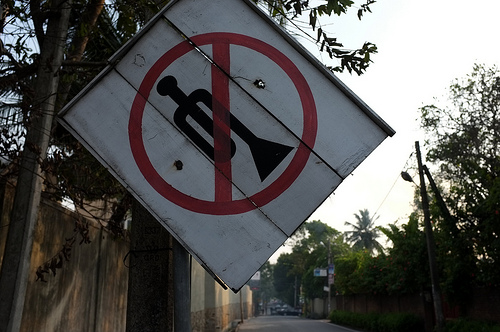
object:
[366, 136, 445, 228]
electric wire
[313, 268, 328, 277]
signs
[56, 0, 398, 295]
signs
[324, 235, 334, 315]
pole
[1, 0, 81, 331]
pole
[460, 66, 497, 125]
green parts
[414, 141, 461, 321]
pole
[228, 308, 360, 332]
street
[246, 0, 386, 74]
tree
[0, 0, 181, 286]
tree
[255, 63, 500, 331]
tree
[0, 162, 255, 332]
fence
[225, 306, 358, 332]
road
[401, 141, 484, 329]
street light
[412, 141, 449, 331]
light post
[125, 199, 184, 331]
pole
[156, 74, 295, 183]
black trumpet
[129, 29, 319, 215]
print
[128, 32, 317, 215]
circle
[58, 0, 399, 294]
planks